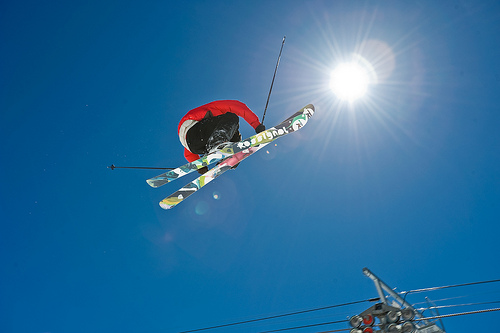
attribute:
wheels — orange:
[361, 312, 379, 331]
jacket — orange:
[176, 98, 268, 163]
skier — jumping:
[176, 97, 264, 174]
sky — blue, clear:
[2, 3, 497, 331]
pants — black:
[182, 115, 250, 158]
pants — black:
[174, 113, 249, 167]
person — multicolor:
[68, 46, 400, 214]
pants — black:
[185, 110, 241, 153]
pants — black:
[184, 113, 256, 160]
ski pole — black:
[262, 32, 287, 129]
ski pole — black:
[107, 159, 175, 174]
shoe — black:
[207, 127, 230, 147]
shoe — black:
[227, 157, 243, 170]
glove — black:
[256, 119, 271, 133]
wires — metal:
[189, 277, 499, 332]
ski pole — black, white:
[259, 36, 286, 123]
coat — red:
[164, 93, 265, 147]